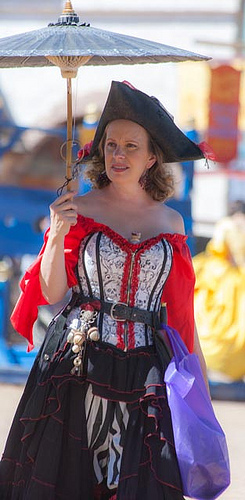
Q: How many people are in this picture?
A: One.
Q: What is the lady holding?
A: An umbrella.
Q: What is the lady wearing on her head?
A: A hat.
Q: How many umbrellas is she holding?
A: One.